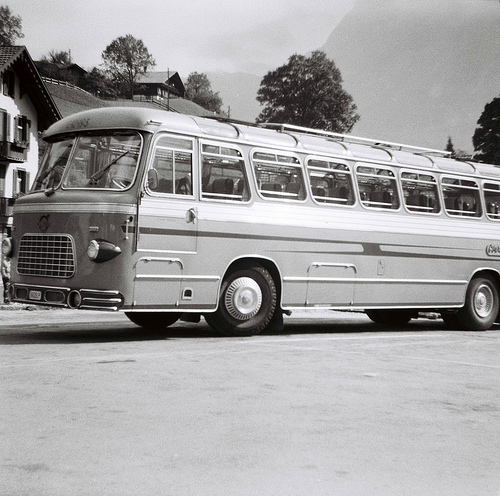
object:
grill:
[16, 233, 76, 279]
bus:
[0, 106, 500, 338]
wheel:
[440, 274, 499, 330]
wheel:
[204, 258, 277, 337]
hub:
[224, 276, 262, 321]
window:
[3, 70, 16, 99]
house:
[0, 43, 65, 230]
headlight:
[2, 238, 12, 256]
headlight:
[86, 238, 99, 260]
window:
[198, 138, 253, 204]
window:
[249, 147, 308, 202]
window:
[307, 158, 356, 206]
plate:
[29, 290, 42, 300]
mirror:
[148, 168, 160, 189]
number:
[66, 117, 90, 129]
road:
[0, 308, 499, 495]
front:
[0, 108, 156, 311]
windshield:
[31, 130, 144, 190]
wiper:
[91, 150, 130, 186]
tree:
[255, 49, 360, 134]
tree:
[98, 34, 157, 102]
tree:
[471, 96, 499, 166]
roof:
[0, 44, 64, 132]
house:
[100, 71, 186, 104]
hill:
[40, 73, 221, 124]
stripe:
[12, 191, 499, 242]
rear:
[449, 156, 499, 330]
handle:
[186, 207, 197, 225]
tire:
[125, 310, 184, 329]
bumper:
[1, 281, 125, 312]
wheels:
[123, 263, 499, 338]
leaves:
[316, 64, 335, 88]